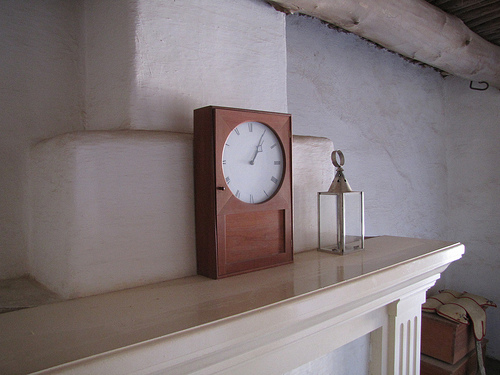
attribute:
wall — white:
[3, 0, 465, 300]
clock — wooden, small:
[189, 102, 297, 281]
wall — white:
[291, 14, 498, 356]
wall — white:
[1, 2, 448, 372]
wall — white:
[305, 36, 454, 173]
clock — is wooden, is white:
[213, 119, 293, 212]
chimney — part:
[81, 14, 338, 259]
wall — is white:
[2, 7, 460, 230]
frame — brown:
[193, 104, 295, 278]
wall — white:
[125, 0, 295, 142]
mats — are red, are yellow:
[419, 278, 499, 344]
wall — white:
[124, 32, 233, 74]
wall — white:
[137, 2, 289, 132]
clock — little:
[171, 97, 312, 272]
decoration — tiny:
[308, 144, 371, 254]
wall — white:
[0, 2, 499, 372]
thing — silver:
[324, 144, 392, 266]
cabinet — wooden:
[182, 89, 344, 298]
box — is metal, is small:
[315, 147, 365, 256]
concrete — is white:
[307, 238, 457, 322]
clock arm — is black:
[251, 127, 264, 168]